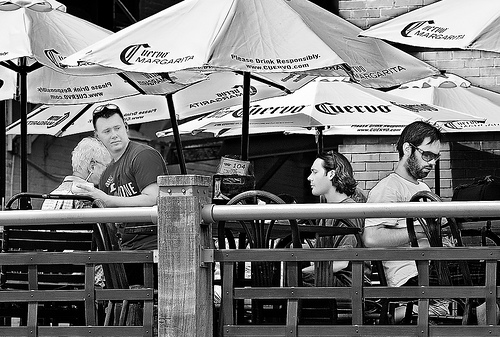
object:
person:
[305, 144, 369, 291]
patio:
[0, 168, 495, 335]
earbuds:
[124, 125, 129, 130]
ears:
[92, 130, 99, 139]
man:
[360, 120, 465, 290]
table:
[212, 205, 364, 245]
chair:
[212, 185, 303, 321]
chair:
[297, 215, 367, 320]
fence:
[3, 167, 499, 334]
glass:
[73, 186, 82, 194]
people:
[38, 104, 461, 296]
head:
[71, 135, 113, 188]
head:
[90, 103, 134, 152]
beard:
[407, 143, 425, 175]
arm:
[82, 180, 158, 206]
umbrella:
[73, 10, 433, 107]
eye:
[420, 149, 430, 161]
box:
[213, 172, 255, 197]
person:
[72, 107, 177, 222]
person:
[40, 134, 122, 209]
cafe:
[0, 3, 498, 335]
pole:
[158, 173, 214, 335]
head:
[399, 121, 443, 180]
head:
[306, 153, 356, 197]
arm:
[359, 225, 426, 247]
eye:
[112, 124, 119, 131]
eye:
[311, 168, 321, 176]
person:
[362, 117, 478, 328]